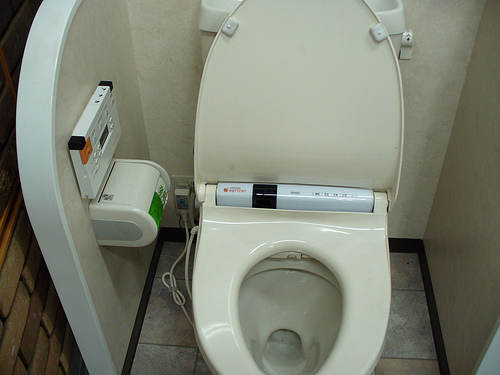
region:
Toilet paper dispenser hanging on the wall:
[97, 156, 179, 243]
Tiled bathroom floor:
[395, 248, 424, 374]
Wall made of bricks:
[12, 256, 44, 368]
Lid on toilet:
[175, 6, 417, 192]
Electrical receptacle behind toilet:
[169, 169, 194, 226]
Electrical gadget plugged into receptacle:
[167, 182, 194, 223]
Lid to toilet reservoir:
[183, 0, 415, 32]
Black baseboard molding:
[413, 241, 453, 374]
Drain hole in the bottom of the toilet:
[252, 313, 314, 369]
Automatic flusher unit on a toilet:
[211, 179, 379, 217]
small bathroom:
[5, 4, 497, 371]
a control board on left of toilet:
[64, 76, 136, 206]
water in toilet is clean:
[246, 314, 325, 371]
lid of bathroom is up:
[182, 0, 410, 194]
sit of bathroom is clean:
[188, 205, 393, 373]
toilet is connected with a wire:
[163, 185, 205, 339]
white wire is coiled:
[154, 265, 193, 325]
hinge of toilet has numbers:
[209, 174, 381, 219]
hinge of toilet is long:
[211, 176, 381, 221]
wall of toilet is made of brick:
[5, 237, 72, 367]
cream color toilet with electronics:
[177, 6, 404, 373]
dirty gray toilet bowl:
[251, 317, 324, 369]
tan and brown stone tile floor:
[394, 318, 434, 370]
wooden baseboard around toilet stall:
[393, 231, 459, 373]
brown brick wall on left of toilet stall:
[6, 288, 51, 370]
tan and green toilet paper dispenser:
[96, 152, 176, 259]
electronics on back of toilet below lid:
[211, 173, 384, 223]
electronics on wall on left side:
[55, 75, 131, 192]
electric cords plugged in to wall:
[158, 179, 200, 348]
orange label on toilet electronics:
[72, 135, 104, 170]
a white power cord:
[153, 218, 198, 327]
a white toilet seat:
[193, 219, 241, 340]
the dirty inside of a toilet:
[257, 276, 314, 372]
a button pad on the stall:
[62, 100, 131, 182]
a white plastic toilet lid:
[201, 32, 421, 197]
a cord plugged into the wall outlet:
[163, 176, 198, 237]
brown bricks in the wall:
[6, 271, 58, 352]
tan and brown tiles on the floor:
[136, 325, 175, 374]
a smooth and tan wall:
[436, 163, 496, 274]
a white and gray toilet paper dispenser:
[99, 164, 168, 251]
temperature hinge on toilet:
[191, 172, 398, 218]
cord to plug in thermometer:
[174, 184, 196, 339]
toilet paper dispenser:
[86, 152, 181, 252]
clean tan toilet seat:
[192, 205, 436, 374]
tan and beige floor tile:
[392, 335, 435, 374]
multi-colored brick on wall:
[6, 287, 63, 373]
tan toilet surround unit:
[20, 12, 499, 325]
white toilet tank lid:
[191, 2, 231, 42]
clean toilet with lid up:
[180, 2, 410, 370]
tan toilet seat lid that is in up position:
[188, 3, 443, 193]